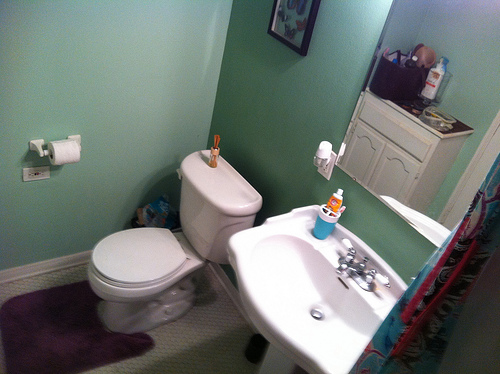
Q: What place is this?
A: Bathroom.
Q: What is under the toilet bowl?
A: A purple bathroom rug.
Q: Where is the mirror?
A: On the wall of a bathroom.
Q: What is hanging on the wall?
A: A picture.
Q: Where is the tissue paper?
A: Hanging on the wall.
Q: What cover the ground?
A: Tiles.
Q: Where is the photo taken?
A: A bathroom.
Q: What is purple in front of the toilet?
A: A rug.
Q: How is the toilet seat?
A: Down.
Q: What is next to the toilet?
A: A sink.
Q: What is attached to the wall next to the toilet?
A: Toilet paper dispenser.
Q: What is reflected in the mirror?
A: Cabinet.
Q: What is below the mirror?
A: Sink.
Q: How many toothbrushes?
A: 1.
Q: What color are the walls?
A: Green.